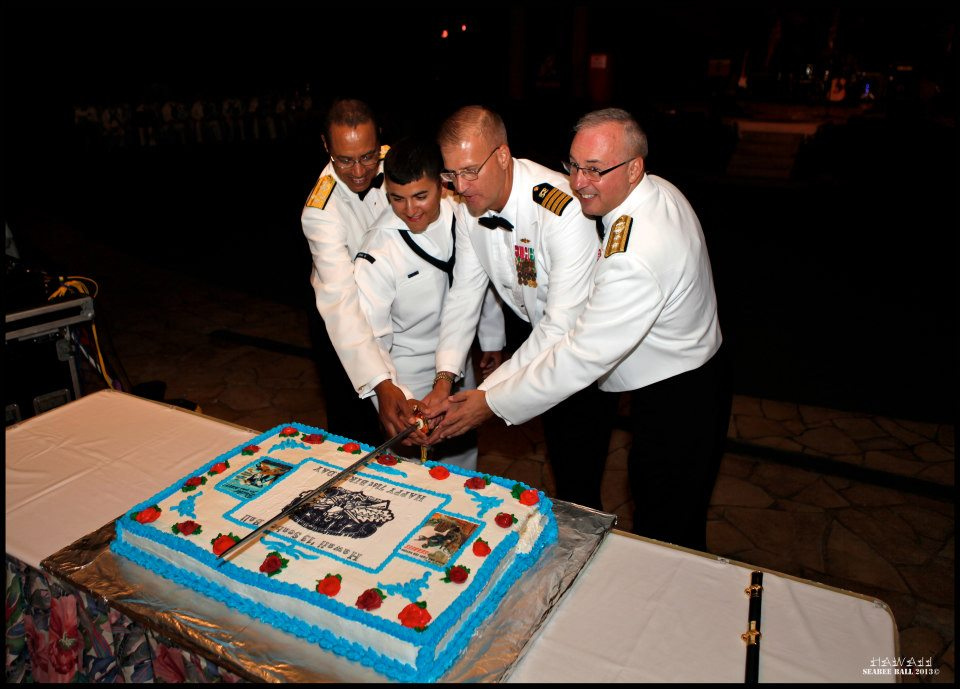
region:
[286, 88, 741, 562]
a group of men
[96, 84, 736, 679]
a group of men cutting a cake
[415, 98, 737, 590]
two men wearing glasses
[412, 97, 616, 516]
a man wearing a bow tie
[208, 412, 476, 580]
a long knife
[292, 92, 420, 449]
a man wearing a white shirt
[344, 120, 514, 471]
a man wearing a sailor uniform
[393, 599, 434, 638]
a red flower on the cake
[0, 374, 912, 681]
white table covering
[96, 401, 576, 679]
blue white and red cake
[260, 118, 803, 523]
people standing at cake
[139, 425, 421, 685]
blue and white cake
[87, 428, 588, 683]
blue frosting on cake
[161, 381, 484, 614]
people hold long knife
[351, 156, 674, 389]
people have white shirts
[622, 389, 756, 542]
man has black pants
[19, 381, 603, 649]
cake on white table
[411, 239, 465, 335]
person wears black tie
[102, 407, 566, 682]
A big cake with blue and white frosting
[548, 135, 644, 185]
A pair of eyeglasses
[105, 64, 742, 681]
Four men are cutting the cake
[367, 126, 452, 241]
Black hair on man's head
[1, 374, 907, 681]
White tablecloth on a table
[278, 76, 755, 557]
Four men are standing together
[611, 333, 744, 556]
A pair of black pants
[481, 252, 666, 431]
White long sleeve of a shirt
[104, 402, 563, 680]
cake on foil on table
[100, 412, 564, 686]
cake on foil is very large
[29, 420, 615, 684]
foil on long table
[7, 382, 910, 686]
long table holds cake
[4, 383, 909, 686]
tablecloth on long table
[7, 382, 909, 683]
tablecloth on table is white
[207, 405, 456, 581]
men using sword to cut cake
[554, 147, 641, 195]
man on right wearing eye glasses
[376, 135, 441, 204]
third man has dark hair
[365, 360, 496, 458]
men's hands are touching sword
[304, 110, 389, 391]
person in white shirt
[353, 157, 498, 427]
person in white shirt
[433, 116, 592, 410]
person in white shirt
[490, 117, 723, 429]
person in white shirt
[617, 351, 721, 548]
the pants are black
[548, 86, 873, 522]
a man in uniform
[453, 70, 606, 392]
a man in uniform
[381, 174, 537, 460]
a man in uniform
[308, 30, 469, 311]
a man in uniform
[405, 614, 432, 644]
a fruit iced on the cake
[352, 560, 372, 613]
a fruit iced on the cake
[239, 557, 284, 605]
a fruit iced on the cake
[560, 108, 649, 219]
The man on the right is wearing glasses.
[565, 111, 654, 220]
The man on the right has short hair.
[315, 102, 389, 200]
The man on the left has short hair.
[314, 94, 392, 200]
The man on the left has black hair.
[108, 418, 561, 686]
The cake has a rectangle shape.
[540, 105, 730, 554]
The man on the right is wearing black pants.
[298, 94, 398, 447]
The man on the left is wearing black pants.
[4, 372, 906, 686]
The table has a white cloth.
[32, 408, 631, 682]
cake on tin foil on table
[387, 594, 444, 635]
red strawberry design on cake icing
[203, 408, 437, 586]
long metal knife slicing into cake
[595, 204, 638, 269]
yellow badge and emblem on white shoulder